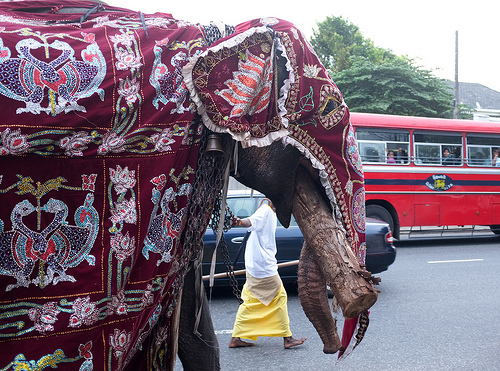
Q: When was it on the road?
A: During the day.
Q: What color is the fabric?
A: Red.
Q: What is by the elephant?
A: A man.